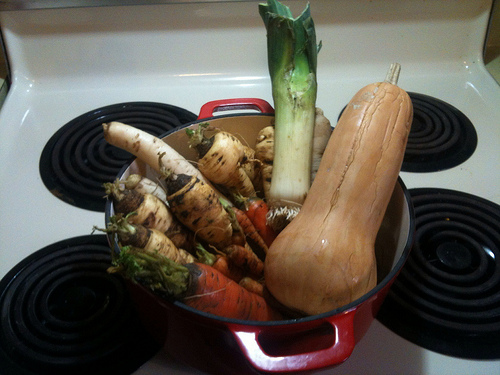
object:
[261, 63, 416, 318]
squash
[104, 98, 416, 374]
pot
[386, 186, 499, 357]
burner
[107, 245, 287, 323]
carrot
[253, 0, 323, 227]
vegetables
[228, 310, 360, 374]
handle